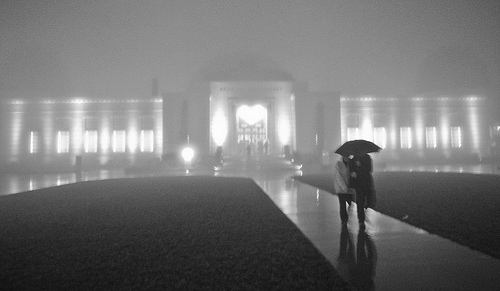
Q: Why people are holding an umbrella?
A: It's raining.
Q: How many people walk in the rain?
A: Two.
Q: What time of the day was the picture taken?
A: At night.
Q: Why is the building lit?
A: Because it's dark outside.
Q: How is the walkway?
A: Wet.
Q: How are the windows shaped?
A: Rectangles.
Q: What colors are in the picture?
A: Black, white and grey.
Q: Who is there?
A: 2 people.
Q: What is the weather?
A: Rainy.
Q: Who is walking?
A: People.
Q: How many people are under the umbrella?
A: Two.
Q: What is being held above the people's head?
A: Umbrella.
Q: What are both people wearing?
A: Coats.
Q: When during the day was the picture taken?
A: Night.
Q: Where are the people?
A: On a sidewalk.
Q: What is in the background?
A: A building.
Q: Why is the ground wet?
A: Rain.